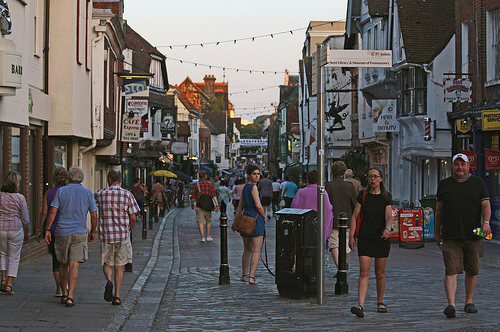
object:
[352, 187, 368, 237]
red purse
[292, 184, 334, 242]
pink shaw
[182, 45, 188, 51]
lights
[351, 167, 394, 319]
woman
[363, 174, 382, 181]
glasses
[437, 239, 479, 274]
shorts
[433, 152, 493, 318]
man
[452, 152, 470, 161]
cap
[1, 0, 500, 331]
scene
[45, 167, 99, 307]
person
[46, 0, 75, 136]
wall